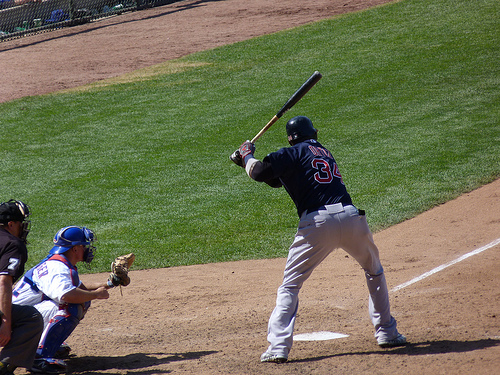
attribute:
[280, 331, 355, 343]
home plate — white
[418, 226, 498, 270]
line — White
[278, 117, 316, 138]
helmet — black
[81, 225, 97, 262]
mask — face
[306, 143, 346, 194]
number — team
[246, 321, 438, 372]
shoes — white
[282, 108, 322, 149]
helmet — black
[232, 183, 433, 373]
pants — white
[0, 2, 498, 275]
grass — green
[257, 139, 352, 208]
shirt — black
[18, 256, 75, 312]
shirt — black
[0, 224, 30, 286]
shirt — black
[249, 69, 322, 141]
bat — black, brown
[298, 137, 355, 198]
number — 34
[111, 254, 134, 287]
glove — brown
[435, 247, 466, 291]
line — white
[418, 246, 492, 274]
line — white